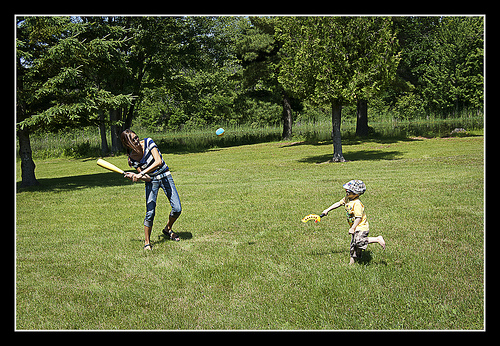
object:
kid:
[323, 180, 385, 265]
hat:
[343, 179, 367, 195]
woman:
[124, 129, 182, 251]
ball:
[215, 127, 225, 136]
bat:
[96, 158, 136, 182]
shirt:
[339, 196, 370, 231]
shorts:
[350, 231, 369, 259]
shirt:
[128, 137, 172, 181]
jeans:
[141, 174, 182, 228]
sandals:
[144, 244, 152, 252]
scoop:
[301, 214, 321, 224]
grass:
[13, 131, 488, 329]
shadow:
[295, 149, 403, 164]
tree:
[273, 17, 399, 165]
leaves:
[277, 17, 399, 106]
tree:
[309, 17, 404, 134]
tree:
[231, 18, 327, 139]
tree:
[16, 16, 202, 155]